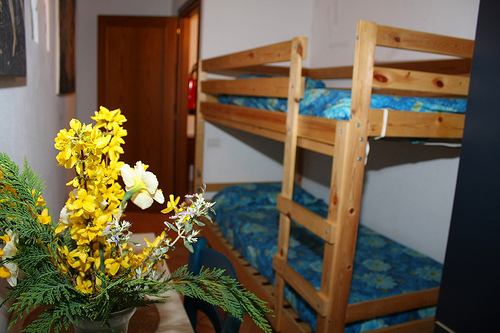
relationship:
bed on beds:
[203, 20, 473, 158] [183, 15, 493, 332]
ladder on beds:
[272, 20, 362, 332] [197, 33, 445, 323]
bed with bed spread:
[201, 179, 456, 329] [206, 181, 443, 325]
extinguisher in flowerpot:
[189, 76, 195, 113] [48, 297, 139, 330]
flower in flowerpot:
[41, 109, 146, 299] [48, 297, 139, 330]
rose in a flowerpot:
[118, 157, 165, 212] [48, 297, 139, 330]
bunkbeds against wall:
[199, 20, 480, 332] [201, 2, 483, 265]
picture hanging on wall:
[37, 0, 81, 102] [255, 0, 334, 40]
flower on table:
[24, 104, 180, 300] [133, 221, 188, 328]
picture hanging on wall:
[57, 0, 82, 100] [3, 2, 81, 251]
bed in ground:
[201, 179, 456, 333] [173, 239, 238, 311]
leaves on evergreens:
[168, 222, 255, 308] [1, 151, 273, 330]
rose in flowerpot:
[118, 157, 165, 212] [48, 297, 139, 330]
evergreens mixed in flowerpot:
[1, 151, 273, 330] [0, 229, 196, 331]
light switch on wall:
[205, 135, 227, 145] [209, 144, 256, 179]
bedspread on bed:
[212, 185, 444, 330] [201, 179, 456, 329]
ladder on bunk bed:
[266, 20, 361, 330] [197, 11, 467, 331]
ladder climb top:
[272, 20, 362, 332] [204, 13, 474, 138]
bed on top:
[195, 45, 455, 332] [193, 16, 474, 146]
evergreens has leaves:
[1, 151, 273, 330] [168, 270, 240, 299]